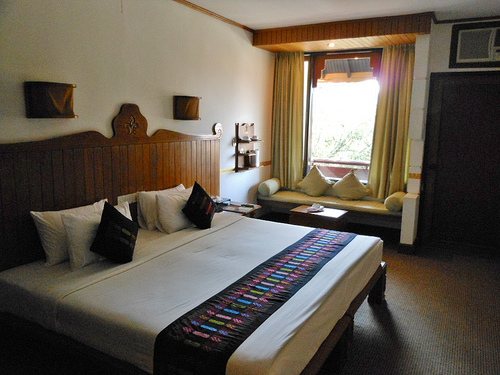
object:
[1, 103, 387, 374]
bed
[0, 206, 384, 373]
sheet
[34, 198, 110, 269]
pillow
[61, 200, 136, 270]
pillow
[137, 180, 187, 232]
pillow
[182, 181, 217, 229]
pillow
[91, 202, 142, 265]
pillow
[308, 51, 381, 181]
window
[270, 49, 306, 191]
curtain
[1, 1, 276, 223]
wall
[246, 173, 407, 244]
sofa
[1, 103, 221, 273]
headboard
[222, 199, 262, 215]
table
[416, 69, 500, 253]
door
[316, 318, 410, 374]
shadow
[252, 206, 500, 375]
carpet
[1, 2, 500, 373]
hotel room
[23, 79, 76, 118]
light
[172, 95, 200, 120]
light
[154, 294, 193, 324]
wrinkle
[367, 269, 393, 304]
leg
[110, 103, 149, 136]
decorative edge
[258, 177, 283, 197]
divan